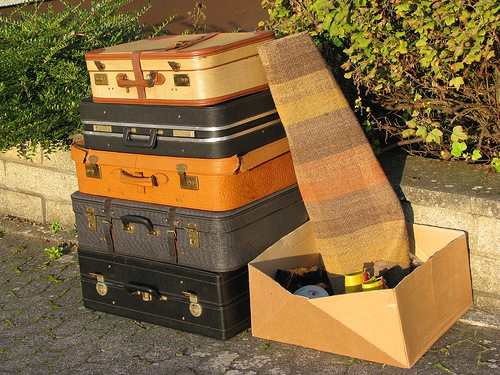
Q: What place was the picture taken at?
A: It was taken at the road.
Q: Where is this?
A: This is at the road.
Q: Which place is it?
A: It is a road.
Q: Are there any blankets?
A: Yes, there is a blanket.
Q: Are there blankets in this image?
A: Yes, there is a blanket.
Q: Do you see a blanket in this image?
A: Yes, there is a blanket.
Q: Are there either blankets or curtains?
A: Yes, there is a blanket.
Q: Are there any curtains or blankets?
A: Yes, there is a blanket.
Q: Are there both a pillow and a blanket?
A: No, there is a blanket but no pillows.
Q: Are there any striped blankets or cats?
A: Yes, there is a striped blanket.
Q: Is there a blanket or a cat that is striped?
A: Yes, the blanket is striped.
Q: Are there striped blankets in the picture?
A: Yes, there is a striped blanket.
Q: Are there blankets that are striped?
A: Yes, there is a blanket that is striped.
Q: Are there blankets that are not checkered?
A: Yes, there is a striped blanket.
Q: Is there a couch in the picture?
A: No, there are no couches.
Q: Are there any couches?
A: No, there are no couches.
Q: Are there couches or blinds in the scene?
A: No, there are no couches or blinds.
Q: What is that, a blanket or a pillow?
A: That is a blanket.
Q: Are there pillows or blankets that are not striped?
A: No, there is a blanket but it is striped.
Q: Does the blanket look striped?
A: Yes, the blanket is striped.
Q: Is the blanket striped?
A: Yes, the blanket is striped.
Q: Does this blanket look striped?
A: Yes, the blanket is striped.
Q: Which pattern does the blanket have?
A: The blanket has striped pattern.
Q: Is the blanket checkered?
A: No, the blanket is striped.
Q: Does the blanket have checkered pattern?
A: No, the blanket is striped.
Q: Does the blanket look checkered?
A: No, the blanket is striped.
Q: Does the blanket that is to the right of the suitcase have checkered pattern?
A: No, the blanket is striped.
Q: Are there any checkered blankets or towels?
A: No, there is a blanket but it is striped.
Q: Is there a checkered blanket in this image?
A: No, there is a blanket but it is striped.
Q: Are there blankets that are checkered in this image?
A: No, there is a blanket but it is striped.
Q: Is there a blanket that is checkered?
A: No, there is a blanket but it is striped.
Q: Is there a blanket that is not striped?
A: No, there is a blanket but it is striped.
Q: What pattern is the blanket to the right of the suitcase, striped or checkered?
A: The blanket is striped.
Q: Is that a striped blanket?
A: Yes, that is a striped blanket.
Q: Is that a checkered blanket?
A: No, that is a striped blanket.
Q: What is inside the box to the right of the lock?
A: The blanket is inside the box.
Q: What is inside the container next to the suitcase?
A: The blanket is inside the box.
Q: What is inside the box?
A: The blanket is inside the box.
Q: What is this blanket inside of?
A: The blanket is inside the box.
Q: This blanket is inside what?
A: The blanket is inside the box.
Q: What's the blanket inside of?
A: The blanket is inside the box.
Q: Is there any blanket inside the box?
A: Yes, there is a blanket inside the box.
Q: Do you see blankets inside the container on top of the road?
A: Yes, there is a blanket inside the box.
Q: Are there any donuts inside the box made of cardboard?
A: No, there is a blanket inside the box.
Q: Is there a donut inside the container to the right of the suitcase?
A: No, there is a blanket inside the box.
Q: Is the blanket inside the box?
A: Yes, the blanket is inside the box.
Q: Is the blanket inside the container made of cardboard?
A: Yes, the blanket is inside the box.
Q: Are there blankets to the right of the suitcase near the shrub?
A: Yes, there is a blanket to the right of the suitcase.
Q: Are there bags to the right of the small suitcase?
A: No, there is a blanket to the right of the suitcase.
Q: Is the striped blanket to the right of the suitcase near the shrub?
A: Yes, the blanket is to the right of the suitcase.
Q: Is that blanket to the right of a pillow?
A: No, the blanket is to the right of the suitcase.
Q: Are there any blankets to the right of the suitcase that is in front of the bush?
A: Yes, there is a blanket to the right of the suitcase.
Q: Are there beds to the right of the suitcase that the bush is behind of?
A: No, there is a blanket to the right of the suitcase.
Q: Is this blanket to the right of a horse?
A: No, the blanket is to the right of a suitcase.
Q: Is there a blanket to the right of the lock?
A: Yes, there is a blanket to the right of the lock.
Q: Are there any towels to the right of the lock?
A: No, there is a blanket to the right of the lock.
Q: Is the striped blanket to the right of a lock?
A: Yes, the blanket is to the right of a lock.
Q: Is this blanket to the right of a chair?
A: No, the blanket is to the right of a lock.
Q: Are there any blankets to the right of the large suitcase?
A: Yes, there is a blanket to the right of the suitcase.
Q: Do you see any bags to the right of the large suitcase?
A: No, there is a blanket to the right of the suitcase.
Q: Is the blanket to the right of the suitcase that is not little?
A: Yes, the blanket is to the right of the suitcase.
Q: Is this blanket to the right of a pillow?
A: No, the blanket is to the right of the suitcase.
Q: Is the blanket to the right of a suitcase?
A: Yes, the blanket is to the right of a suitcase.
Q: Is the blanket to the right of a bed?
A: No, the blanket is to the right of a suitcase.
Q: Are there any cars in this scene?
A: No, there are no cars.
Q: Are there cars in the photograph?
A: No, there are no cars.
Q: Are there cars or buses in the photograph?
A: No, there are no cars or buses.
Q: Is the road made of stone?
A: Yes, the road is made of stone.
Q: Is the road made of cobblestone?
A: No, the road is made of stone.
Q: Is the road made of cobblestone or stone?
A: The road is made of stone.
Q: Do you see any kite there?
A: No, there are no kites.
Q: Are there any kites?
A: No, there are no kites.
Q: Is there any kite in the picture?
A: No, there are no kites.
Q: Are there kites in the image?
A: No, there are no kites.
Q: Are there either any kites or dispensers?
A: No, there are no kites or dispensers.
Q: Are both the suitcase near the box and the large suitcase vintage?
A: Yes, both the suitcase and the suitcase are vintage.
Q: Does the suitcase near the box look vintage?
A: Yes, the suitcase is vintage.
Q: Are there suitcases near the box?
A: Yes, there is a suitcase near the box.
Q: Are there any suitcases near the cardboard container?
A: Yes, there is a suitcase near the box.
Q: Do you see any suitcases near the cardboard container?
A: Yes, there is a suitcase near the box.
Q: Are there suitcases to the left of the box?
A: Yes, there is a suitcase to the left of the box.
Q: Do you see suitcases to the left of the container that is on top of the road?
A: Yes, there is a suitcase to the left of the box.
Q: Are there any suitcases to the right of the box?
A: No, the suitcase is to the left of the box.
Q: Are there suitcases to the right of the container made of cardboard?
A: No, the suitcase is to the left of the box.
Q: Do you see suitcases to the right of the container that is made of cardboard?
A: No, the suitcase is to the left of the box.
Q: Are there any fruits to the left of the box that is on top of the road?
A: No, there is a suitcase to the left of the box.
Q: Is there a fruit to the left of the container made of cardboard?
A: No, there is a suitcase to the left of the box.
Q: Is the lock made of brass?
A: Yes, the lock is made of brass.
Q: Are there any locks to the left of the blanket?
A: Yes, there is a lock to the left of the blanket.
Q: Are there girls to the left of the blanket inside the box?
A: No, there is a lock to the left of the blanket.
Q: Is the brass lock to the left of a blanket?
A: Yes, the lock is to the left of a blanket.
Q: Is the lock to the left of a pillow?
A: No, the lock is to the left of a blanket.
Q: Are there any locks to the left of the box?
A: Yes, there is a lock to the left of the box.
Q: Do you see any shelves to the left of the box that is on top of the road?
A: No, there is a lock to the left of the box.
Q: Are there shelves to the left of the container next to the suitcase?
A: No, there is a lock to the left of the box.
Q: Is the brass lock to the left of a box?
A: Yes, the lock is to the left of a box.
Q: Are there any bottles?
A: No, there are no bottles.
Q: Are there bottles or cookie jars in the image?
A: No, there are no bottles or cookie jars.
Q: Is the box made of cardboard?
A: Yes, the box is made of cardboard.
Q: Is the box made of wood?
A: No, the box is made of cardboard.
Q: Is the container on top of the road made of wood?
A: No, the box is made of cardboard.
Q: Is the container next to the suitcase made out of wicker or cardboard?
A: The box is made of cardboard.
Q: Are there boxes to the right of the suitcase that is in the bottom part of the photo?
A: Yes, there is a box to the right of the suitcase.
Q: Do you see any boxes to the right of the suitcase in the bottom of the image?
A: Yes, there is a box to the right of the suitcase.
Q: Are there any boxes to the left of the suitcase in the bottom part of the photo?
A: No, the box is to the right of the suitcase.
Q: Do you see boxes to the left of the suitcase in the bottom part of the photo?
A: No, the box is to the right of the suitcase.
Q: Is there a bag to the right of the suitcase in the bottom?
A: No, there is a box to the right of the suitcase.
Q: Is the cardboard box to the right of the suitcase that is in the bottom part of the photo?
A: Yes, the box is to the right of the suitcase.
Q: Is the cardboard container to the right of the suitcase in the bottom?
A: Yes, the box is to the right of the suitcase.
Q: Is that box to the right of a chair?
A: No, the box is to the right of the suitcase.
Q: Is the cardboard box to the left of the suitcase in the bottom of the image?
A: No, the box is to the right of the suitcase.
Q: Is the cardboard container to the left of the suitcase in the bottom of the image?
A: No, the box is to the right of the suitcase.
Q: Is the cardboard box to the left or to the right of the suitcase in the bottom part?
A: The box is to the right of the suitcase.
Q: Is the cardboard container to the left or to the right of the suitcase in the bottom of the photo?
A: The box is to the right of the suitcase.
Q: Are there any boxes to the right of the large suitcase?
A: Yes, there is a box to the right of the suitcase.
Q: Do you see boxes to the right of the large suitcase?
A: Yes, there is a box to the right of the suitcase.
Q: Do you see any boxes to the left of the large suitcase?
A: No, the box is to the right of the suitcase.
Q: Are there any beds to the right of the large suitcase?
A: No, there is a box to the right of the suitcase.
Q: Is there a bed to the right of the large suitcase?
A: No, there is a box to the right of the suitcase.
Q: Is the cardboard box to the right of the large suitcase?
A: Yes, the box is to the right of the suitcase.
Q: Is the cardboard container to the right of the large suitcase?
A: Yes, the box is to the right of the suitcase.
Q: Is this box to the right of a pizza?
A: No, the box is to the right of the suitcase.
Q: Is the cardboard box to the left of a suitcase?
A: No, the box is to the right of a suitcase.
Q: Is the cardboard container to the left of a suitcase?
A: No, the box is to the right of a suitcase.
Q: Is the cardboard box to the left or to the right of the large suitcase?
A: The box is to the right of the suitcase.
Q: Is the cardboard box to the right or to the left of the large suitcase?
A: The box is to the right of the suitcase.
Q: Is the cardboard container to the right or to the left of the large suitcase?
A: The box is to the right of the suitcase.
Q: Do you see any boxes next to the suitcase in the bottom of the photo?
A: Yes, there is a box next to the suitcase.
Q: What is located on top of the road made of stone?
A: The box is on top of the road.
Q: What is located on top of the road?
A: The box is on top of the road.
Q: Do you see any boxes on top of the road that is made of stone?
A: Yes, there is a box on top of the road.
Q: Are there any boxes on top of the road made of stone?
A: Yes, there is a box on top of the road.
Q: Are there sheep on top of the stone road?
A: No, there is a box on top of the road.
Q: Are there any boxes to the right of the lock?
A: Yes, there is a box to the right of the lock.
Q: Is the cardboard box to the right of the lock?
A: Yes, the box is to the right of the lock.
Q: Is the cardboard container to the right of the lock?
A: Yes, the box is to the right of the lock.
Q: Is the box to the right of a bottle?
A: No, the box is to the right of the lock.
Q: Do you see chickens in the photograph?
A: No, there are no chickens.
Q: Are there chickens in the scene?
A: No, there are no chickens.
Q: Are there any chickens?
A: No, there are no chickens.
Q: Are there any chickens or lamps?
A: No, there are no chickens or lamps.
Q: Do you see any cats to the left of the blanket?
A: No, there is a suitcase to the left of the blanket.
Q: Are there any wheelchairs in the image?
A: No, there are no wheelchairs.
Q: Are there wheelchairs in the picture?
A: No, there are no wheelchairs.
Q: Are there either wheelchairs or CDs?
A: No, there are no wheelchairs or cds.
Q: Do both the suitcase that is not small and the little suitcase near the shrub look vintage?
A: Yes, both the suitcase and the suitcase are vintage.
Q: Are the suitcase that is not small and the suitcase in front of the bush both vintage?
A: Yes, both the suitcase and the suitcase are vintage.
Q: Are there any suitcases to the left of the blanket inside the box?
A: Yes, there is a suitcase to the left of the blanket.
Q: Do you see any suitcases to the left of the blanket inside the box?
A: Yes, there is a suitcase to the left of the blanket.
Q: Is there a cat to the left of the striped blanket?
A: No, there is a suitcase to the left of the blanket.